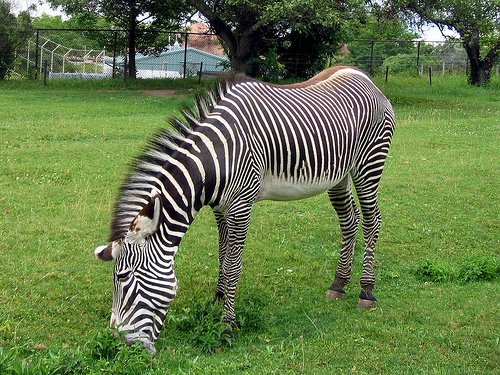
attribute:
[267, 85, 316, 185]
stripe — black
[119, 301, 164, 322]
stripe — black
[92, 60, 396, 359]
zebra — alone, striped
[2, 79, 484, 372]
grass — green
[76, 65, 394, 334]
zebra — black, white